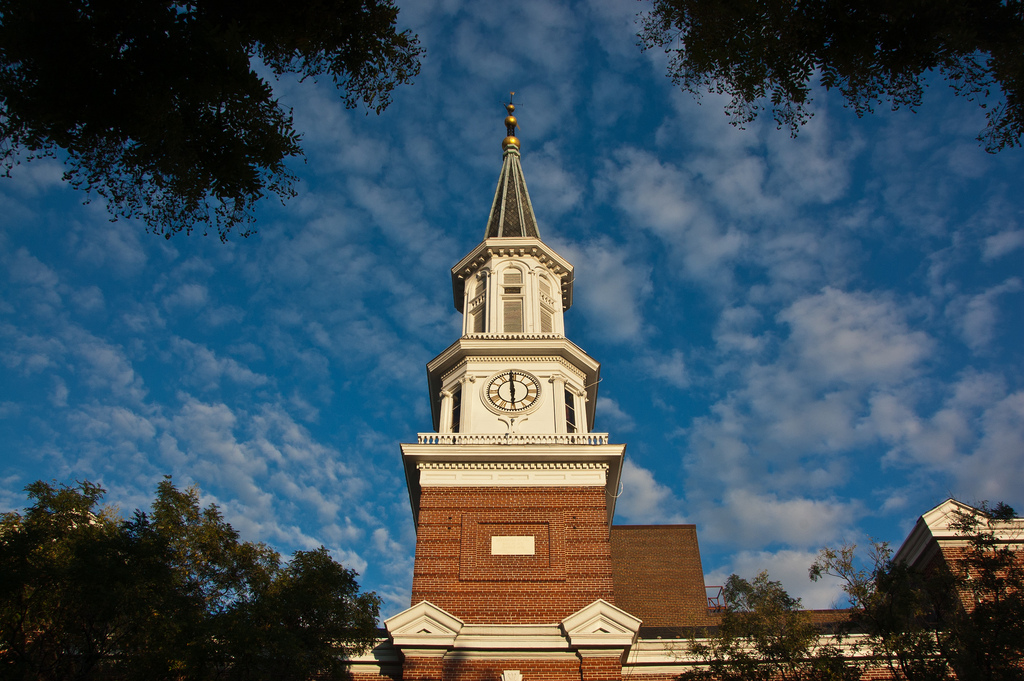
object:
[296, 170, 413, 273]
cloud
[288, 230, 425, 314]
cloud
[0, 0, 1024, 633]
sky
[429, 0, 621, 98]
cloud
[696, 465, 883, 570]
cloud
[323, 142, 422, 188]
cloud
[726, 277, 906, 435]
cloud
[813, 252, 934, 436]
cloud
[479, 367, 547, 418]
clock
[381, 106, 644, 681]
buidling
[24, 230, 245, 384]
clouds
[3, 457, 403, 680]
tree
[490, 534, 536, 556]
sign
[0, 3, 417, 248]
tree branch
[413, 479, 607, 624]
wall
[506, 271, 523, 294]
window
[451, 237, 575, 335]
crown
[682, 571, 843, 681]
tree